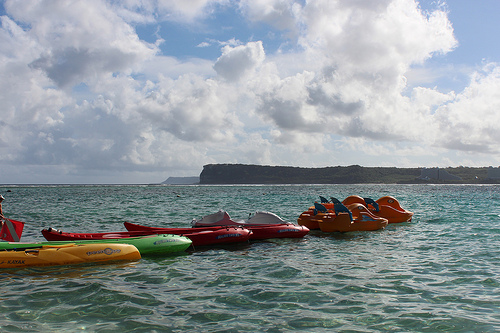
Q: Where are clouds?
A: In the sky.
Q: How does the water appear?
A: Calm.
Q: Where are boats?
A: On the water.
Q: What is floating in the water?
A: Many boats.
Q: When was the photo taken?
A: Daytime.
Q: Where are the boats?
A: In the water.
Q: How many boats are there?
A: Seven.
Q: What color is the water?
A: Bluish green.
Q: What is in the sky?
A: Clouds.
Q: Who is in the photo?
A: Nobody.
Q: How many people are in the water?
A: None.